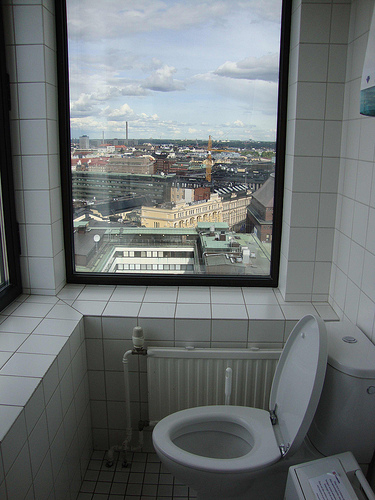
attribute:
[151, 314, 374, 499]
toilet — white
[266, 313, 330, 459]
lid — white, raised, up, open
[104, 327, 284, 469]
radiator — white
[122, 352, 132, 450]
pipe — white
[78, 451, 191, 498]
tile — white, grey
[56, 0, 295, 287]
frame — black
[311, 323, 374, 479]
tank — white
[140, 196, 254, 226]
building — tan, large, yellow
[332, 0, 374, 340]
wall — white, tiled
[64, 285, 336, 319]
sill — tiled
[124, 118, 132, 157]
building — tall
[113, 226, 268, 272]
roof — green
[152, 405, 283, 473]
seat — open, white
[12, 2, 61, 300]
wall — white, tiled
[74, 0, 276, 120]
sky — cloudy